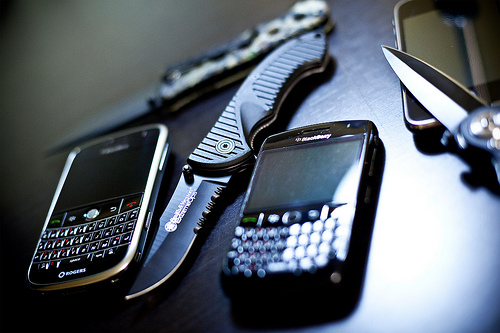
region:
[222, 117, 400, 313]
a black smart phone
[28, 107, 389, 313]
two black smart phones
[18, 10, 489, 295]
a bunch of knives and smart phones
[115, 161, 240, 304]
a knife blade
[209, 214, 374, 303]
phone keys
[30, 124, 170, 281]
cellphone on the table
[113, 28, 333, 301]
Knife on the table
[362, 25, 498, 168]
Knife on the table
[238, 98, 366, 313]
cellphone on the desk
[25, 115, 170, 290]
cellphone on the desk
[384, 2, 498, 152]
cellphone on the desk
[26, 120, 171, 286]
The cell phone on the left.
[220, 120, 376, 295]
The cell phone in the middle.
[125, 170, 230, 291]
The blade of the knife in between the phones.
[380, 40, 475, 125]
The blade of the knife on the right.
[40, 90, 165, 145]
The blade of the knife at the top.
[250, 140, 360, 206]
The screen of the phone in the middle.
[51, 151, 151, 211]
The screen of the phone on the left.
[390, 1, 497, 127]
The cell phone on the right.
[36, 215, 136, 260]
The buttons of the phone on the left.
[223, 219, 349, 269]
The buttons of the phone in the middle.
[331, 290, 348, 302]
motorcycle in a field with gravel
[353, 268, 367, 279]
motorcycle in a field with gravel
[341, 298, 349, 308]
motorcycle in a field with gravel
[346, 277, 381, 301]
motorcycle in a field with gravel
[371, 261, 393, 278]
motorcycle in a field with gravel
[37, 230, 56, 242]
White button on a phone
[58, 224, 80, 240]
White button on a phone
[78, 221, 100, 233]
White button on a phone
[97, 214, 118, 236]
White button on a phone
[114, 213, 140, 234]
White button on a phone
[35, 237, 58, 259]
White button on a phone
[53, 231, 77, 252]
White button on a phone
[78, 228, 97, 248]
White button on a phone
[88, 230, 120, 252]
White button on a phone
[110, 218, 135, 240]
White button on a phone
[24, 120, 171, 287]
the silver phone with keys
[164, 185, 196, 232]
the words on the knife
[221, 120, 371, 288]
the phone is a blackberry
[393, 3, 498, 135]
the touchscreen phone